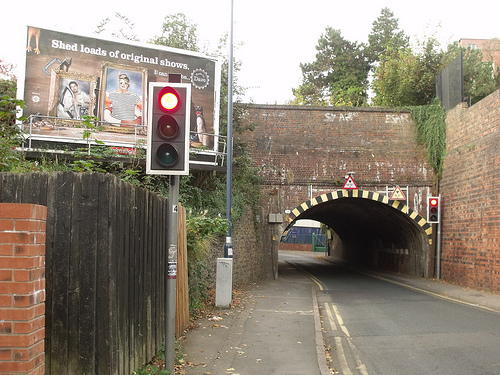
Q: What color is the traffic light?
A: Red.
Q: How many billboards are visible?
A: One.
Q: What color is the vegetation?
A: Green.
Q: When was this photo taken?
A: Outside, during the daytime.